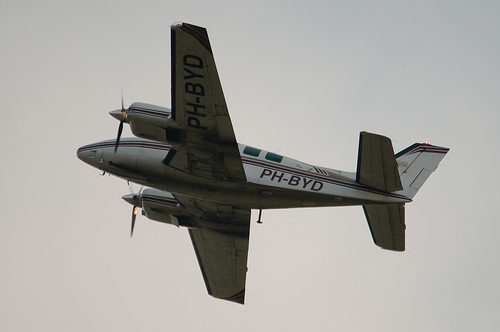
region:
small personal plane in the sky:
[108, 35, 429, 272]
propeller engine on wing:
[102, 96, 247, 151]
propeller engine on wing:
[124, 182, 219, 229]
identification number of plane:
[247, 158, 357, 205]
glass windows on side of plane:
[227, 130, 281, 162]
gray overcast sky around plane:
[10, 11, 487, 284]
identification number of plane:
[182, 45, 209, 131]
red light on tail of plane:
[407, 135, 432, 150]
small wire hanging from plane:
[250, 208, 267, 230]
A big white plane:
[42, 75, 475, 251]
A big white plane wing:
[160, 26, 240, 136]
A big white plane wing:
[181, 220, 271, 296]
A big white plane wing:
[340, 110, 396, 185]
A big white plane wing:
[345, 200, 411, 245]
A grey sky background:
[275, 245, 395, 330]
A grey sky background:
[425, 180, 492, 315]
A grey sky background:
[270, 17, 425, 99]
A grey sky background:
[13, 15, 110, 97]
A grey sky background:
[18, 168, 133, 303]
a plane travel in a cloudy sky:
[61, 7, 469, 323]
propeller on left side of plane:
[100, 73, 138, 160]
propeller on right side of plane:
[117, 180, 146, 236]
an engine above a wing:
[106, 83, 174, 162]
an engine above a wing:
[117, 180, 239, 264]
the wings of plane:
[160, 13, 262, 312]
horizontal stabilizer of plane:
[351, 123, 417, 263]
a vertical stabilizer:
[396, 129, 453, 199]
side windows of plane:
[238, 135, 293, 173]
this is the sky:
[255, 34, 307, 69]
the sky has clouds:
[40, 223, 74, 270]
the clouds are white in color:
[39, 264, 89, 300]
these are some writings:
[255, 163, 334, 199]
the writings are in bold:
[256, 162, 326, 203]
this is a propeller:
[119, 177, 146, 239]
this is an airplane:
[46, 22, 479, 312]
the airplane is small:
[67, 20, 444, 303]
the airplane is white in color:
[247, 164, 257, 191]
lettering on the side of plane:
[256, 160, 330, 193]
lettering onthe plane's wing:
[175, 42, 208, 129]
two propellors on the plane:
[105, 82, 143, 237]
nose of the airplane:
[78, 138, 88, 162]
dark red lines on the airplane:
[94, 130, 396, 205]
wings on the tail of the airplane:
[348, 136, 411, 251]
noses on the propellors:
[109, 106, 129, 210]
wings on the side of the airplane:
[173, 23, 266, 299]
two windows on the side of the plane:
[242, 143, 284, 168]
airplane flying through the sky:
[80, 16, 457, 311]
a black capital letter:
[257, 164, 271, 180]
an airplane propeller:
[108, 94, 131, 154]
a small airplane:
[74, 18, 454, 317]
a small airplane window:
[242, 145, 266, 155]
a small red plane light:
[419, 140, 431, 148]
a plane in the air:
[69, 31, 404, 272]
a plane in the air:
[127, 56, 400, 261]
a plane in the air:
[90, 31, 417, 329]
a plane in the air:
[90, 28, 425, 288]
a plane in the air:
[69, 5, 411, 322]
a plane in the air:
[99, 19, 468, 308]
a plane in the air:
[107, 28, 489, 319]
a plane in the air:
[77, 11, 450, 328]